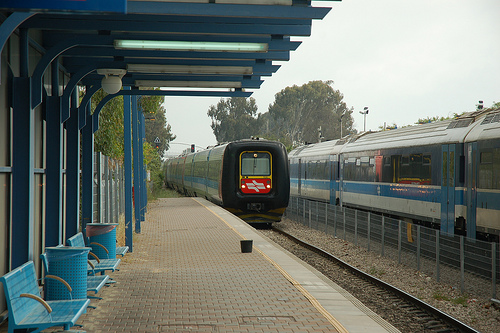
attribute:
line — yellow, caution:
[233, 247, 317, 304]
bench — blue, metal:
[0, 263, 90, 331]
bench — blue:
[69, 228, 126, 275]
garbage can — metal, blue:
[85, 220, 117, 257]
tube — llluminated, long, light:
[119, 37, 270, 56]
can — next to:
[45, 248, 90, 299]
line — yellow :
[189, 191, 341, 331]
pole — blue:
[121, 85, 133, 250]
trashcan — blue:
[39, 242, 93, 314]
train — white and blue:
[272, 134, 487, 240]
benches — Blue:
[3, 231, 128, 327]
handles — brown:
[17, 240, 107, 312]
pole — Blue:
[116, 89, 136, 256]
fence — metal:
[246, 163, 491, 319]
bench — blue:
[32, 219, 146, 307]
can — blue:
[30, 233, 109, 313]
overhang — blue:
[4, 0, 334, 100]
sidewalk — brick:
[79, 178, 345, 329]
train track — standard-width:
[255, 222, 474, 331]